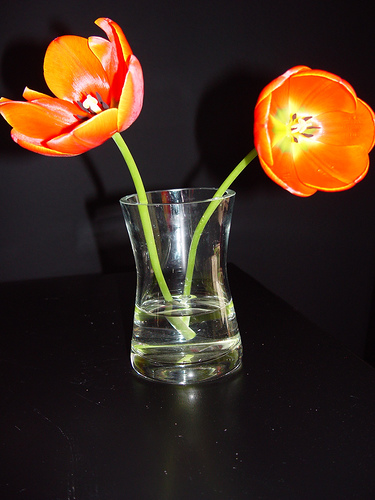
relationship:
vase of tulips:
[119, 185, 245, 385] [0, 14, 373, 198]